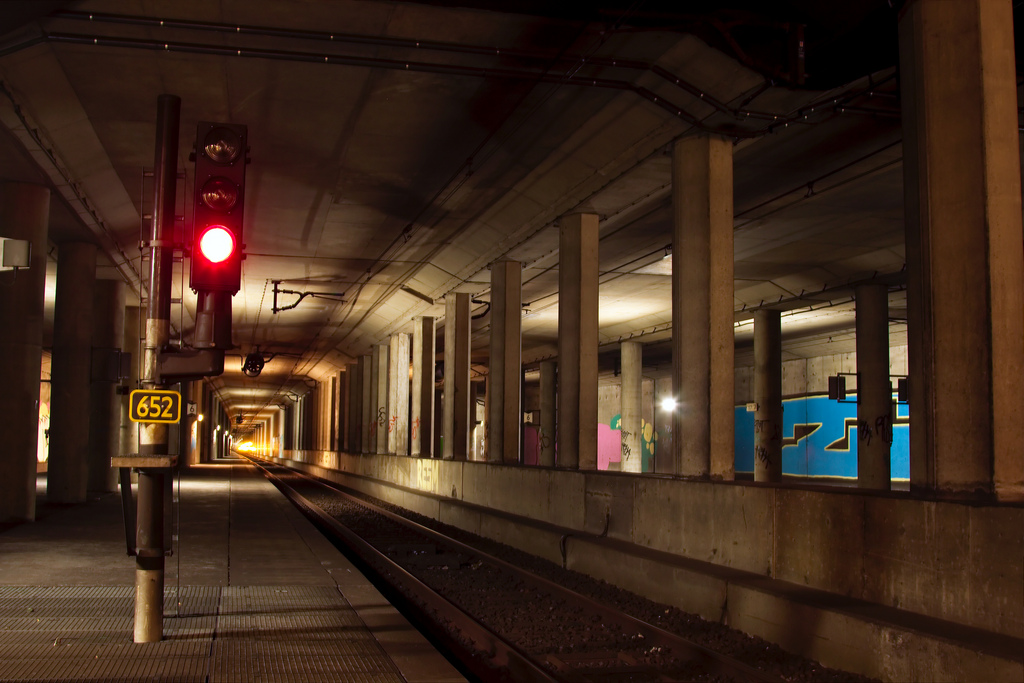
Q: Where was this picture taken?
A: Terminal.